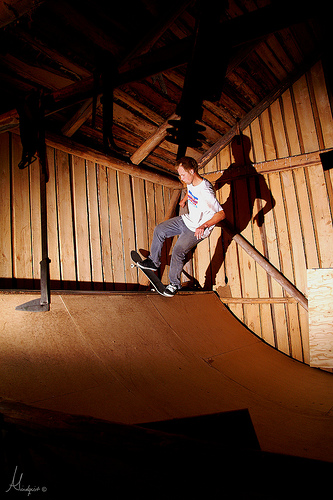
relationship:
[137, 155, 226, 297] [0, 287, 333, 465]
boarder skating on ramp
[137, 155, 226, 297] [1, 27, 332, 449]
boarder skating building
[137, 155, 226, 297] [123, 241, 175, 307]
boarder riding a skateboard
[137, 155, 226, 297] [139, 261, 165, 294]
boarder on skateboard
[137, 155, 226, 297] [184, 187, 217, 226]
boarder wearing shirt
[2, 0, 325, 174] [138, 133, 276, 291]
ceiling above ceiling shadow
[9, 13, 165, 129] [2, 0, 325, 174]
beam on ceiling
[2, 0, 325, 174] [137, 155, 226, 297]
ceiling over boarder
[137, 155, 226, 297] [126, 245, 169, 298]
boarder riding a skateboard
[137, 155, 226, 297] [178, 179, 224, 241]
boarder wearing shirt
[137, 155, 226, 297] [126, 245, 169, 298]
boarder on skateboard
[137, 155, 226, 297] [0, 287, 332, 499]
boarder on ramp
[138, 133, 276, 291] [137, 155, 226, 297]
ceiling shadow of boarder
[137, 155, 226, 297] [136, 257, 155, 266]
boarder wearing sneaker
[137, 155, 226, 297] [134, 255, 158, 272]
boarder wearing shoes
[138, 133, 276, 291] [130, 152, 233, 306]
ceiling shadow of skateboarder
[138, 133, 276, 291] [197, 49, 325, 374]
ceiling shadow on wall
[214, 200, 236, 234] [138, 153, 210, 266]
arm of boarder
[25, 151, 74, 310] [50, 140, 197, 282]
pole by wall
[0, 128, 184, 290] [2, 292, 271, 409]
wall by ramp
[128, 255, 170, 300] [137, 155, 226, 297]
shoes on boarder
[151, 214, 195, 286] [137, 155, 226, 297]
pants of boarder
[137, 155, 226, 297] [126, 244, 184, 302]
boarder on skateboard